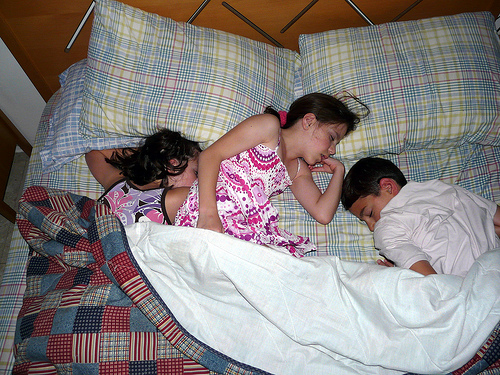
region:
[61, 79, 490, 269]
This is a family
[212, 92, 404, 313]
This is a young girl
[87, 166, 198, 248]
The girl is wearing purple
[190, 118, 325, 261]
The girl is wearing pink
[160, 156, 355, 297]
The pattern is paisley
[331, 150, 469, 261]
This is a young boy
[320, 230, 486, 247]
The shirt is white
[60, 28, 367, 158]
These are soft pillows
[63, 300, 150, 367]
The blanket is quilted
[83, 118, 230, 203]
This is brown hair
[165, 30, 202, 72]
part of a pillow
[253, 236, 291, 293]
part of a sheet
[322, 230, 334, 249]
part of a sheet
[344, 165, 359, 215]
hair of a boy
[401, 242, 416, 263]
part of a sleeve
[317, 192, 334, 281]
part of an elbow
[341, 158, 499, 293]
Boy in white shirt sleeping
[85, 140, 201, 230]
Girl in purple shirt sleeping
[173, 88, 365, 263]
Girl in pink dress sleeping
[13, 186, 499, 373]
Red, white and blue patch blanket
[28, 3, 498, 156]
three big blue pillows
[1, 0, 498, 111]
brown wood head board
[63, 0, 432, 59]
silver rods on wood board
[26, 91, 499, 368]
Bed with blue bed sheets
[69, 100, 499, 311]
Group of three kids sleeping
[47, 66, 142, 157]
Small blue pillow under the big pillow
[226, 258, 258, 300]
part of a sheey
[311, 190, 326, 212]
part of an elbow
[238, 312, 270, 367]
part of a sheet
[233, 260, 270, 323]
part of a sheet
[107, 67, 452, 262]
kids sleeping on bed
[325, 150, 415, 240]
head of the boy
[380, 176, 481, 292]
white shirt on boy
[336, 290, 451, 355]
blanket on the boy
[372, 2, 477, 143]
pillow above the boy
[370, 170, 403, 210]
ear of the boy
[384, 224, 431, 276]
sleeve of the shirt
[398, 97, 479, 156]
blue and yellow lines on pillow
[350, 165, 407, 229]
boy with eyes closed in the photo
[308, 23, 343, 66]
corner of the pillow